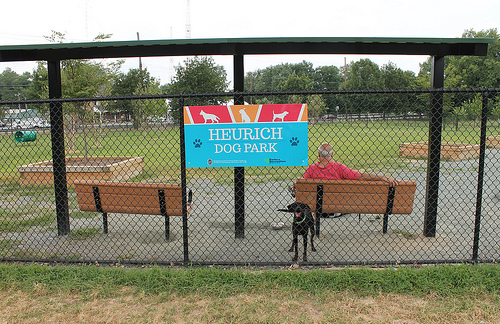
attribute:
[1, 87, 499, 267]
fence — metal, chainlink, black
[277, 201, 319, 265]
dog — medium-sized, black, standing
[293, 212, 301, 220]
tongue — pink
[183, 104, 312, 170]
sign — black, white, orange, red, blue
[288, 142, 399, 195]
man — sitting, white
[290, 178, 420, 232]
bench — metal, wood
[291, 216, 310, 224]
collar — blue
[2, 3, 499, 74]
sky — gray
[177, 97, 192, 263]
post — metal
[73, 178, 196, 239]
bench — wood, empty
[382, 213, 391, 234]
leg — metal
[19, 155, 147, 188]
planter — wooden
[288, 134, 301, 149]
icon — pawprint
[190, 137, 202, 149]
icon — pawprint